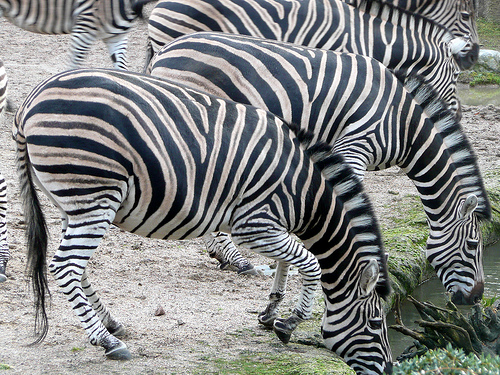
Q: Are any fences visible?
A: No, there are no fences.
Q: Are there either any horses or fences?
A: No, there are no fences or horses.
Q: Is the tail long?
A: Yes, the tail is long.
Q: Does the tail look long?
A: Yes, the tail is long.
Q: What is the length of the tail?
A: The tail is long.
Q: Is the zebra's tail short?
A: No, the tail is long.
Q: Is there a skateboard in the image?
A: No, there are no skateboards.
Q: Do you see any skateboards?
A: No, there are no skateboards.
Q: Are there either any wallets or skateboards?
A: No, there are no skateboards or wallets.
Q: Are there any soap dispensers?
A: No, there are no soap dispensers.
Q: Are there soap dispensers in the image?
A: No, there are no soap dispensers.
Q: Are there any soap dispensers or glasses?
A: No, there are no soap dispensers or glasses.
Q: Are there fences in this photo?
A: No, there are no fences.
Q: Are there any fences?
A: No, there are no fences.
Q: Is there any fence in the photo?
A: No, there are no fences.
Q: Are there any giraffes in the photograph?
A: No, there are no giraffes.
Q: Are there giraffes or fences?
A: No, there are no giraffes or fences.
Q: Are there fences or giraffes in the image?
A: No, there are no giraffes or fences.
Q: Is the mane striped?
A: Yes, the mane is striped.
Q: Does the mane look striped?
A: Yes, the mane is striped.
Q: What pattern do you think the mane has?
A: The mane has striped pattern.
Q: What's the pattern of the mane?
A: The mane is striped.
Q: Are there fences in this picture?
A: No, there are no fences.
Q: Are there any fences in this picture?
A: No, there are no fences.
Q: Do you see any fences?
A: No, there are no fences.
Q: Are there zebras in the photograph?
A: Yes, there is a zebra.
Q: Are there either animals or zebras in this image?
A: Yes, there is a zebra.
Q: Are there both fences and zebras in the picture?
A: No, there is a zebra but no fences.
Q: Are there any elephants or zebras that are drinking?
A: Yes, the zebra is drinking.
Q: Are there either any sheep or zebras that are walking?
A: Yes, the zebra is walking.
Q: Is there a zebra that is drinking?
A: Yes, there is a zebra that is drinking.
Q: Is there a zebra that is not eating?
A: Yes, there is a zebra that is drinking.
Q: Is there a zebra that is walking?
A: Yes, there is a zebra that is walking.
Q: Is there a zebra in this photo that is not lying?
A: Yes, there is a zebra that is walking.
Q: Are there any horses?
A: No, there are no horses.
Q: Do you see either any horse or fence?
A: No, there are no horses or fences.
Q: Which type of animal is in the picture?
A: The animal is a zebra.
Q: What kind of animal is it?
A: The animal is a zebra.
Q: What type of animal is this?
A: This is a zebra.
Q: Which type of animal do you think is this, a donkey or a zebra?
A: This is a zebra.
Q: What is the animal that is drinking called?
A: The animal is a zebra.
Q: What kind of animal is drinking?
A: The animal is a zebra.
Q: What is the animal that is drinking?
A: The animal is a zebra.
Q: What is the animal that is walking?
A: The animal is a zebra.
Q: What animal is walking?
A: The animal is a zebra.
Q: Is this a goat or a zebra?
A: This is a zebra.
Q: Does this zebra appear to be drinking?
A: Yes, the zebra is drinking.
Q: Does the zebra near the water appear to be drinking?
A: Yes, the zebra is drinking.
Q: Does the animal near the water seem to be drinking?
A: Yes, the zebra is drinking.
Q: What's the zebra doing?
A: The zebra is drinking.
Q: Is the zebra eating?
A: No, the zebra is drinking.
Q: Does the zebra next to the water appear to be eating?
A: No, the zebra is drinking.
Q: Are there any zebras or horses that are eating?
A: No, there is a zebra but it is drinking.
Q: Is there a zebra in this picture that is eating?
A: No, there is a zebra but it is drinking.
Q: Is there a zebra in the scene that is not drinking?
A: No, there is a zebra but it is drinking.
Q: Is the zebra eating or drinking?
A: The zebra is drinking.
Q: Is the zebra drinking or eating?
A: The zebra is drinking.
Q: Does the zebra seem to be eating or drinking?
A: The zebra is drinking.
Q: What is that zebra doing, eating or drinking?
A: The zebra is drinking.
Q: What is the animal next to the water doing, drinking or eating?
A: The zebra is drinking.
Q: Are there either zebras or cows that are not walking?
A: No, there is a zebra but it is walking.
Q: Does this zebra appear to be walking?
A: Yes, the zebra is walking.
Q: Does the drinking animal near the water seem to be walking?
A: Yes, the zebra is walking.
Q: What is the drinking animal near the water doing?
A: The zebra is walking.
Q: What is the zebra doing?
A: The zebra is walking.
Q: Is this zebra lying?
A: No, the zebra is walking.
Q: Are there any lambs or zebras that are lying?
A: No, there is a zebra but it is walking.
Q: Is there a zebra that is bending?
A: No, there is a zebra but it is walking.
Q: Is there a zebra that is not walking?
A: No, there is a zebra but it is walking.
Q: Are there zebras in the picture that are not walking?
A: No, there is a zebra but it is walking.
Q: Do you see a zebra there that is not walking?
A: No, there is a zebra but it is walking.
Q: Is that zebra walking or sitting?
A: The zebra is walking.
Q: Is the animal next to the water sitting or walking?
A: The zebra is walking.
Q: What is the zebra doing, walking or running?
A: The zebra is walking.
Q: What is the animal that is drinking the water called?
A: The animal is a zebra.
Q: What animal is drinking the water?
A: The animal is a zebra.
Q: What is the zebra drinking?
A: The zebra is drinking water.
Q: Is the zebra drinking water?
A: Yes, the zebra is drinking water.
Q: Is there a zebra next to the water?
A: Yes, there is a zebra next to the water.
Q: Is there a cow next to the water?
A: No, there is a zebra next to the water.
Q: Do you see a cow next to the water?
A: No, there is a zebra next to the water.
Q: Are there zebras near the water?
A: Yes, there is a zebra near the water.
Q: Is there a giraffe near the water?
A: No, there is a zebra near the water.